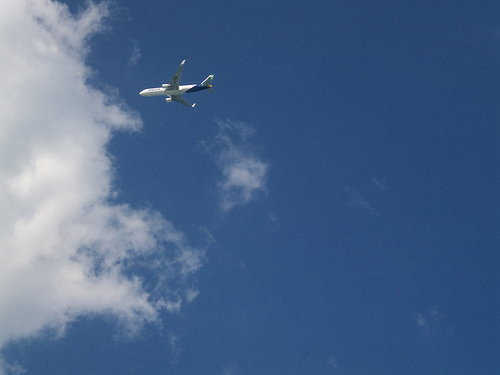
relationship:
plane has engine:
[130, 54, 223, 108] [166, 98, 172, 102]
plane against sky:
[130, 54, 223, 108] [255, 15, 439, 116]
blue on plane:
[190, 73, 220, 102] [130, 54, 223, 108]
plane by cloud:
[130, 54, 223, 108] [5, 3, 124, 353]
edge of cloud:
[74, 3, 138, 362] [5, 3, 124, 353]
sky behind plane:
[255, 15, 439, 116] [130, 54, 223, 108]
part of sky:
[86, 3, 357, 57] [255, 15, 439, 116]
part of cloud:
[86, 3, 357, 57] [5, 3, 124, 353]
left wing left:
[172, 56, 190, 70] [178, 60, 185, 69]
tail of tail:
[190, 73, 220, 102] [201, 75, 214, 92]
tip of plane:
[137, 87, 146, 101] [130, 54, 223, 108]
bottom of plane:
[142, 88, 211, 101] [130, 54, 223, 108]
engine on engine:
[160, 82, 175, 91] [162, 84, 170, 88]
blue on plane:
[189, 81, 206, 96] [130, 54, 223, 108]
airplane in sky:
[130, 54, 223, 108] [255, 15, 439, 116]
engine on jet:
[166, 98, 172, 102] [130, 54, 223, 108]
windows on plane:
[146, 87, 164, 94] [130, 54, 223, 108]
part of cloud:
[86, 3, 357, 57] [56, 1, 110, 42]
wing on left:
[170, 56, 187, 87] [172, 56, 190, 70]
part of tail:
[198, 72, 214, 83] [190, 73, 220, 102]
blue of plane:
[189, 81, 206, 96] [130, 54, 223, 108]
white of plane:
[139, 83, 182, 102] [130, 54, 223, 108]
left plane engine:
[172, 56, 190, 70] [160, 82, 175, 91]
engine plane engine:
[166, 98, 172, 102] [165, 95, 177, 105]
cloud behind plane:
[195, 108, 276, 220] [139, 60, 214, 108]